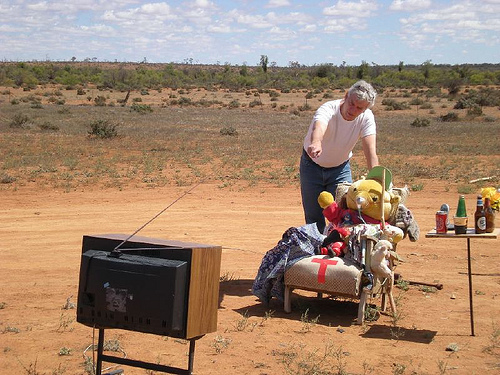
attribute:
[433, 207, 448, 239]
can — aluminum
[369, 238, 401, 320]
animal — stuffed, white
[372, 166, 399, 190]
hat — green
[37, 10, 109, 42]
clouds —  white 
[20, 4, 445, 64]
sky — blue 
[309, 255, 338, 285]
cross — red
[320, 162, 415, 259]
animal — stuffed, yellow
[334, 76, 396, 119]
hair — grey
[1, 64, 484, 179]
bushes — green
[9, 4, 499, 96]
sky — blue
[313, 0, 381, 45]
clouds — white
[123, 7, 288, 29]
clouds — white 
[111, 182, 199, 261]
antenna — metal, long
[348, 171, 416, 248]
teddy bear — large, golden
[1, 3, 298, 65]
clouds — white 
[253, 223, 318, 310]
cloth — blue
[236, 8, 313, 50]
clouds — white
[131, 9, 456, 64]
sky — blue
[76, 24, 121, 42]
white clouds — white 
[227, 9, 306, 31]
white clouds — white 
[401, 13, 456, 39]
white clouds — white 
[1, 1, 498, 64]
blue sky — clear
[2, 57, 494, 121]
foliage — green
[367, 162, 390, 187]
cap — green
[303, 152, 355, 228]
jeans — blue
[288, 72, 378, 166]
t-shirt — short sleeve, cotton , white 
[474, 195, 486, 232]
bottle — glass, brown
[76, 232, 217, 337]
tv — brown and black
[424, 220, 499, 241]
table — wooden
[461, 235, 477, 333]
pole — thin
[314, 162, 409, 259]
bear — yellow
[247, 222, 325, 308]
shirt — blue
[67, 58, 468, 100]
bushels — in distance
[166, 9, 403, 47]
clouds — white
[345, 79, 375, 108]
hair — gray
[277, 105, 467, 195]
shirt — red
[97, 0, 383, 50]
clouds — white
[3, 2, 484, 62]
sky — blue